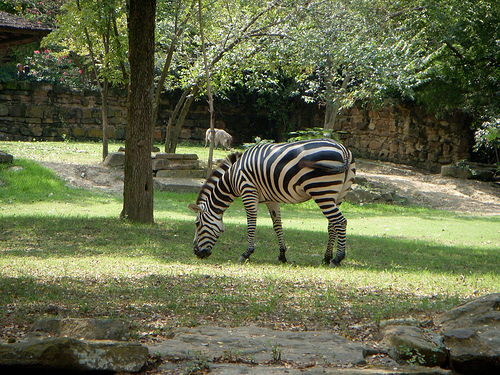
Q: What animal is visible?
A: A zebra.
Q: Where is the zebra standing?
A: On the grass.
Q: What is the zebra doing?
A: Grazing.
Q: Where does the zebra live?
A: The zoo.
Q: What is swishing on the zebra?
A: Tail.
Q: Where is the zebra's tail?
A: To the left.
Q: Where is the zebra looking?
A: Downward.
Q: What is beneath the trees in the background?
A: Rocks.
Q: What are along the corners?
A: Rocks.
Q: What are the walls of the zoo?
A: Rocks.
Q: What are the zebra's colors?
A: Black and white.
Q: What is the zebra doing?
A: Eating grass.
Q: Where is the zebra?
A: In a park.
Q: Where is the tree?
A: To the left of the zebra?.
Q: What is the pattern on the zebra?
A: Stripes.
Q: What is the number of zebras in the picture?
A: One.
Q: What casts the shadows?
A: Trees.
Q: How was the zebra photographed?
A: From the side.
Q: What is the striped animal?
A: Zebra.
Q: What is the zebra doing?
A: Grazing.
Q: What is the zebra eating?
A: Grass.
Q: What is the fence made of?
A: Stone.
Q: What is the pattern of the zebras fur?
A: Striped.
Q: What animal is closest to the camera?
A: Zebra.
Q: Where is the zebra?
A: On the grass.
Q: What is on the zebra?
A: Stripes.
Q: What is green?
A: Grass.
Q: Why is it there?
A: Eating.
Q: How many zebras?
A: 1.